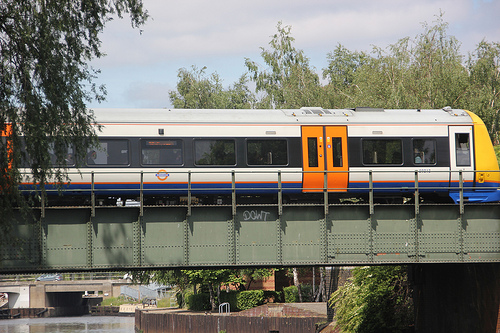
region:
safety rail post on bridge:
[448, 165, 473, 225]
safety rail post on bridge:
[409, 164, 429, 223]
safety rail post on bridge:
[359, 160, 386, 223]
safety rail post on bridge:
[315, 163, 340, 223]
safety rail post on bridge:
[269, 160, 297, 224]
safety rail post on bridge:
[221, 160, 245, 227]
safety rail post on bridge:
[177, 161, 204, 227]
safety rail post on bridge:
[129, 161, 156, 224]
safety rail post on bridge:
[81, 165, 111, 221]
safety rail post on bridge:
[31, 158, 57, 226]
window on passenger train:
[416, 130, 456, 170]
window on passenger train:
[372, 130, 414, 172]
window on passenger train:
[344, 130, 374, 172]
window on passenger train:
[240, 127, 295, 169]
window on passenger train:
[183, 129, 244, 169]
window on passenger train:
[137, 127, 189, 175]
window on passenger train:
[73, 136, 135, 170]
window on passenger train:
[328, 129, 348, 169]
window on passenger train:
[306, 127, 323, 175]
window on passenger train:
[451, 128, 476, 170]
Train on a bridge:
[20, 106, 494, 187]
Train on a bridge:
[246, 89, 494, 201]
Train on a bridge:
[3, 100, 219, 193]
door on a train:
[295, 113, 350, 202]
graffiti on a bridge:
[236, 205, 278, 227]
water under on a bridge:
[64, 310, 112, 330]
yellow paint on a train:
[463, 108, 499, 184]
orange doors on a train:
[299, 118, 349, 198]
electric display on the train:
[143, 136, 180, 148]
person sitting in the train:
[407, 140, 428, 169]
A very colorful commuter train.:
[5, 102, 499, 201]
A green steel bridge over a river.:
[2, 165, 498, 279]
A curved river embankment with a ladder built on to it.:
[132, 301, 335, 331]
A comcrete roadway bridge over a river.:
[3, 275, 166, 315]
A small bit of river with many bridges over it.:
[1, 315, 141, 331]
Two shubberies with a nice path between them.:
[235, 287, 307, 309]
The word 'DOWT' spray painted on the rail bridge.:
[237, 208, 274, 222]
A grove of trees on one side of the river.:
[163, 20, 498, 160]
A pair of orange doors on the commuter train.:
[294, 121, 351, 194]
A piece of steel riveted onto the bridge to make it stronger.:
[328, 230, 371, 255]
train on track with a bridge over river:
[7, 99, 498, 206]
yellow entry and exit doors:
[296, 123, 353, 203]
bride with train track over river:
[4, 205, 498, 275]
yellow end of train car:
[470, 112, 499, 194]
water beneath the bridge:
[3, 306, 136, 331]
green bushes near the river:
[186, 286, 306, 309]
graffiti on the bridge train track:
[236, 206, 277, 226]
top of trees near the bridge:
[172, 33, 498, 103]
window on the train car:
[188, 134, 240, 168]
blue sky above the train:
[105, 33, 260, 100]